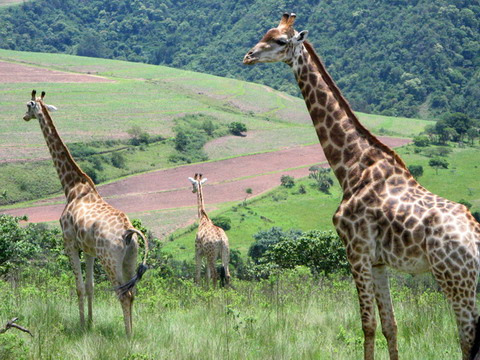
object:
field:
[0, 32, 477, 357]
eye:
[274, 38, 286, 46]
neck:
[285, 60, 404, 194]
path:
[0, 136, 413, 240]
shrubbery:
[0, 212, 345, 290]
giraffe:
[187, 172, 230, 290]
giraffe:
[23, 89, 149, 336]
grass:
[66, 266, 474, 359]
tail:
[105, 227, 148, 299]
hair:
[105, 264, 147, 302]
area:
[0, 56, 114, 83]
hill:
[0, 47, 432, 200]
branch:
[0, 317, 33, 337]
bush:
[279, 174, 295, 189]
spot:
[371, 190, 412, 219]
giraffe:
[243, 12, 479, 359]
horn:
[187, 177, 197, 185]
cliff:
[2, 179, 479, 360]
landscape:
[0, 0, 479, 360]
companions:
[15, 67, 278, 337]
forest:
[0, 0, 479, 122]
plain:
[4, 56, 479, 236]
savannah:
[189, 56, 480, 356]